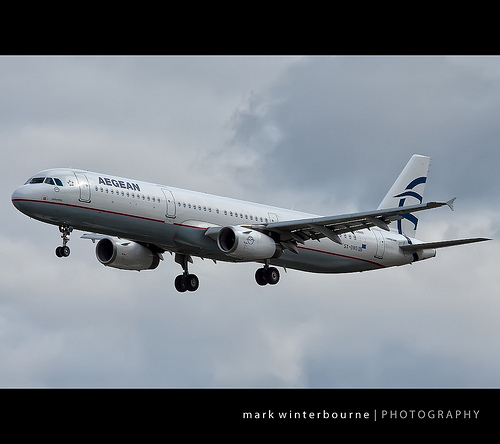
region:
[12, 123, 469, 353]
Plane has landing gear down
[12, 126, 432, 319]
Plane is grey, red, and white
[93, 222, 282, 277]
Plane has two engines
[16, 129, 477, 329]
Plane is at a slight upward angle in the sky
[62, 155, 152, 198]
AEGEAN is on the side of the plane in dark blue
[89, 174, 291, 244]
The plane has many small windows on its side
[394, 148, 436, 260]
The tail has a large blue symbol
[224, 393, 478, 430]
mark winterbourne Photography is in white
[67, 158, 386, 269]
The plane has three doors on its left side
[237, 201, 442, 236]
The wings of the plane are grey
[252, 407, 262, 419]
the white letter A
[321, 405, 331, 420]
the white letter B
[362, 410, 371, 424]
the white letter E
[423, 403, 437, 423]
the white letter G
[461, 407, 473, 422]
the white letter H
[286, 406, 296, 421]
the white letter I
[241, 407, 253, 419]
the white letter M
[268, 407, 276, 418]
the white letter K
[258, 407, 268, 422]
the white letter R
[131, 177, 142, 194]
the blue letter N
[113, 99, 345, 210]
the sky is cloudy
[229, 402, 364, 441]
the photographer is mark winterbourne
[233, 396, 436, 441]
the font is white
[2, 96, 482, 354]
this is a passenger jet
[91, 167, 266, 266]
the airline is aegean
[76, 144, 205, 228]
the font is blue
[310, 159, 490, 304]
the tail has blue logo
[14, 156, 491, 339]
three wheels are down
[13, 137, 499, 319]
the jet is white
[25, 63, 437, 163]
large gray sky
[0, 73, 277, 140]
beautiful white clouds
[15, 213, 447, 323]
two large engines on large jet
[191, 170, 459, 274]
very large jet wing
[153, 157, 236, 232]
middle door on a large jet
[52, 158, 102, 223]
front door on a large jet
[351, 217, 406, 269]
back door on a large jet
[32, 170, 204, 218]
jet with the letter a on it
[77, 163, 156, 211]
jet with the letter e on it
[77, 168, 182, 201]
jet with the letter g on it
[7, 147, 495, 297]
a plane white and gray flying in the air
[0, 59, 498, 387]
a sky with dark clouds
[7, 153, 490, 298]
a single plane flying in the air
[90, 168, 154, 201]
word AEGEAN on the plane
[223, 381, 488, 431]
a watermark that says MARK WINTERBOURNE PHOTOGRAPHY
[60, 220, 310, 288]
two plane engines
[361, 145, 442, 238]
a plane's tail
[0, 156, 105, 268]
a plane's nose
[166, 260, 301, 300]
a plane's landing wheels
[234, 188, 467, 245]
a plane's side wing